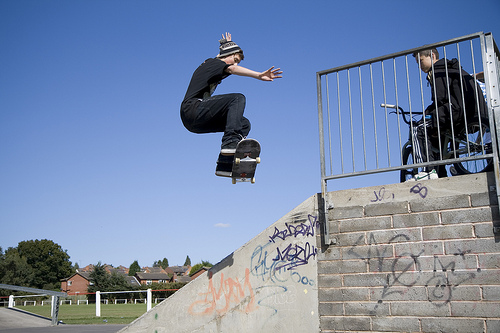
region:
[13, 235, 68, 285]
a large green tree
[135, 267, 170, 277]
the roof of a home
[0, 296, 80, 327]
part of a skateboard ramp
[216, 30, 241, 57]
a boy's black and white cap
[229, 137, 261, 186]
a long black skateboard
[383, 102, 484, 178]
a boy's bike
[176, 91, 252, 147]
a boy's jean pants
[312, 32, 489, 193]
a black rail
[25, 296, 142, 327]
a section of green grass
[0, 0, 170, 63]
part of a blue sky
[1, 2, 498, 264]
blue of daytime sky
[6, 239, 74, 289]
green leaves on tree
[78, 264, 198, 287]
roof tops of houses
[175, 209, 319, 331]
graffiti on cement wall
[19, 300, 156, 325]
surface of green grass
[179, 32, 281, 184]
man crouched over skateboard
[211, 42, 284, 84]
extended arm of skateboarder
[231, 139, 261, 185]
underside of airborne skateboard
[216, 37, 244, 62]
hat on skaters head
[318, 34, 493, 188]
metal poles on railing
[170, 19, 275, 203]
skater jumping in the air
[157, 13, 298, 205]
skater performing a trick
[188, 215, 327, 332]
writing on the cement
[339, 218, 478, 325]
writing on the brick wall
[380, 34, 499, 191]
person on a bicycle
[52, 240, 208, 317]
row of houses in the distance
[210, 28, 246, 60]
hat on a skater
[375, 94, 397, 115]
white handle of a handlebar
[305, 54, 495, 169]
metal poles in a guard rail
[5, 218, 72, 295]
bushy green tree by houses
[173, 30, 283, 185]
a skateboarder in the air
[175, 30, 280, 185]
a skateboarder wearing black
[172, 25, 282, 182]
a skateboarder performing tricks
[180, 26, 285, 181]
a man on a skateboard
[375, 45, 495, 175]
a man on a bicycle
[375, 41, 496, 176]
a man looking left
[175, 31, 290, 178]
a man in the air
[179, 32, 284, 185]
a man wearing a hat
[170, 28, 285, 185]
a skateboarder suspended in the air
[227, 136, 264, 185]
a skateboard in the air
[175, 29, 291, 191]
skate boarder jumping into air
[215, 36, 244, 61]
black and white knit beanie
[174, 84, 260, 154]
black denim boys jeans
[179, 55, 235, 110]
black casual tee shirt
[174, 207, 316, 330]
graffiti on side of skate ramp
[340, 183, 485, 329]
graffiti on side of brick wall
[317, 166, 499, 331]
brick wall with graffiti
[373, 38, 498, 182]
boy sitting on bicycle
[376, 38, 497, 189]
boy watching skate boarder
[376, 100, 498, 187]
bicycle on top of brick wall